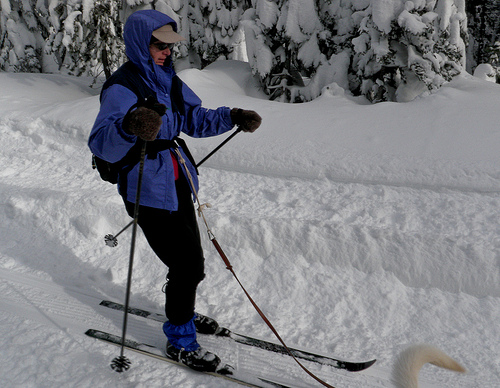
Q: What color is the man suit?
A: Blue.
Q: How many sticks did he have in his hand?
A: Two.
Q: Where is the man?
A: At a ski resort.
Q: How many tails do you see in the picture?
A: One.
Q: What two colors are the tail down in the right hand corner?
A: Brown and white.